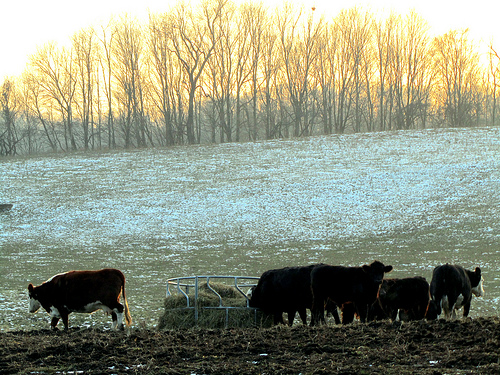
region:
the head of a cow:
[23, 278, 41, 316]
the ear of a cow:
[26, 280, 35, 292]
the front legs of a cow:
[45, 309, 72, 336]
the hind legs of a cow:
[101, 300, 128, 331]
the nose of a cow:
[26, 306, 36, 315]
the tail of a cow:
[120, 277, 135, 329]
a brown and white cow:
[21, 263, 143, 342]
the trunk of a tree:
[181, 85, 201, 148]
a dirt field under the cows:
[1, 326, 497, 373]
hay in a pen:
[156, 278, 260, 333]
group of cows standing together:
[11, 242, 488, 336]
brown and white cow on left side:
[14, 258, 135, 331]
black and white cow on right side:
[432, 255, 483, 320]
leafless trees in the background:
[6, 6, 494, 143]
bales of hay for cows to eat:
[152, 276, 256, 333]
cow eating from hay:
[238, 262, 312, 314]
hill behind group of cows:
[3, 143, 499, 309]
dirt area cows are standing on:
[9, 315, 489, 366]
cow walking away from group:
[419, 247, 491, 314]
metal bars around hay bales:
[171, 265, 267, 335]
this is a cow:
[0, 254, 154, 371]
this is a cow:
[233, 243, 328, 345]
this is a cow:
[295, 253, 395, 328]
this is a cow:
[375, 236, 435, 337]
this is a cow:
[430, 243, 497, 326]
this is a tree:
[24, 53, 81, 150]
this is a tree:
[55, 31, 126, 153]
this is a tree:
[121, 26, 158, 161]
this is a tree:
[153, 0, 215, 145]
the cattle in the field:
[243, 257, 485, 329]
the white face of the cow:
[470, 269, 487, 298]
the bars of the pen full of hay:
[160, 273, 267, 327]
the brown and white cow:
[25, 259, 131, 337]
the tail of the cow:
[120, 274, 135, 326]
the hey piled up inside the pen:
[165, 280, 257, 328]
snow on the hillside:
[205, 178, 432, 245]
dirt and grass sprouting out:
[160, 332, 437, 374]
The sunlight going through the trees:
[0, 9, 498, 101]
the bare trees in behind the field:
[0, 36, 497, 143]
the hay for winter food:
[157, 282, 254, 328]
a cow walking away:
[25, 269, 130, 330]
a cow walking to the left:
[25, 269, 130, 335]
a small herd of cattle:
[247, 262, 489, 329]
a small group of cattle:
[251, 259, 483, 329]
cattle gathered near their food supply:
[248, 262, 483, 329]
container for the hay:
[161, 275, 270, 330]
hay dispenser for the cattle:
[157, 275, 274, 326]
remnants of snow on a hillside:
[4, 129, 497, 252]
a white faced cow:
[431, 262, 488, 322]